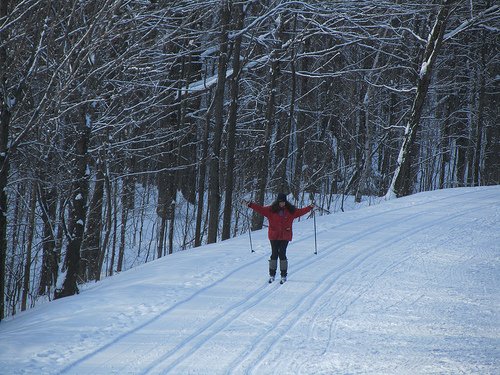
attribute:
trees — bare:
[59, 9, 276, 142]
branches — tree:
[124, 48, 156, 88]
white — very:
[196, 352, 222, 366]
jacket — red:
[242, 193, 318, 251]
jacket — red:
[245, 203, 318, 244]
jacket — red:
[245, 199, 317, 244]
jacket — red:
[240, 196, 318, 247]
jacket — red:
[245, 196, 322, 246]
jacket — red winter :
[250, 204, 315, 242]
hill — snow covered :
[341, 190, 482, 368]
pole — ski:
[307, 214, 326, 261]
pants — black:
[263, 235, 293, 279]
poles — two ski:
[239, 207, 324, 267]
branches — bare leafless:
[76, 27, 231, 153]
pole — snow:
[240, 204, 268, 262]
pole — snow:
[311, 210, 323, 260]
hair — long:
[276, 182, 295, 195]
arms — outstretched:
[232, 193, 317, 225]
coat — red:
[250, 200, 308, 252]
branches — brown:
[155, 53, 183, 101]